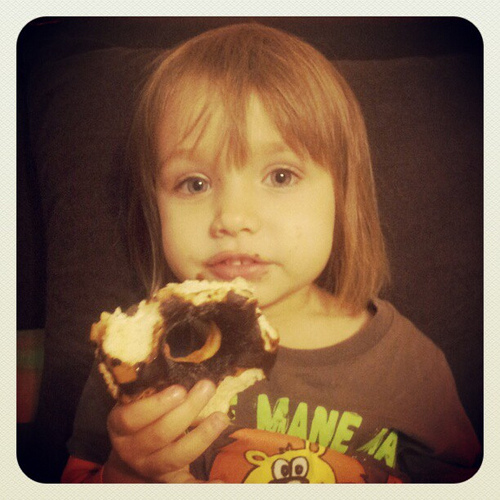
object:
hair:
[116, 21, 392, 319]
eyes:
[169, 171, 212, 198]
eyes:
[261, 164, 303, 191]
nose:
[207, 177, 263, 238]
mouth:
[202, 245, 275, 279]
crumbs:
[193, 271, 205, 283]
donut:
[87, 273, 280, 437]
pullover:
[63, 279, 482, 493]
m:
[250, 393, 290, 439]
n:
[310, 402, 339, 457]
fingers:
[113, 378, 217, 456]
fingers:
[108, 383, 190, 438]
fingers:
[137, 408, 231, 476]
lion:
[209, 424, 371, 486]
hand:
[99, 375, 228, 484]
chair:
[29, 46, 483, 482]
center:
[161, 314, 225, 367]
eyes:
[271, 455, 308, 477]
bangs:
[156, 62, 334, 173]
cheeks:
[273, 216, 335, 276]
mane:
[252, 390, 362, 458]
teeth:
[224, 258, 253, 268]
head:
[134, 24, 353, 315]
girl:
[64, 25, 480, 499]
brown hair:
[107, 25, 394, 320]